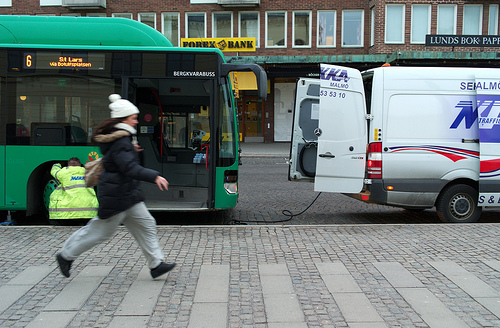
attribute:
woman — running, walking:
[81, 106, 170, 264]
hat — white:
[110, 84, 143, 120]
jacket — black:
[93, 120, 137, 212]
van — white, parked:
[321, 60, 484, 224]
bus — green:
[55, 21, 247, 226]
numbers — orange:
[19, 52, 52, 92]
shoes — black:
[43, 251, 195, 286]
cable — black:
[254, 178, 338, 242]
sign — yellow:
[182, 23, 283, 65]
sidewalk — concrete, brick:
[189, 207, 399, 307]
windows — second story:
[220, 8, 396, 61]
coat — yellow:
[50, 162, 120, 223]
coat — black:
[95, 122, 145, 214]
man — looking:
[56, 147, 102, 211]